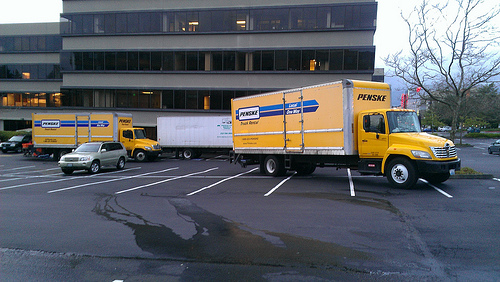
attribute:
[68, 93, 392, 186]
trucks — parked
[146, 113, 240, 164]
truck — white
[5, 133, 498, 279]
parking lot — outdoors